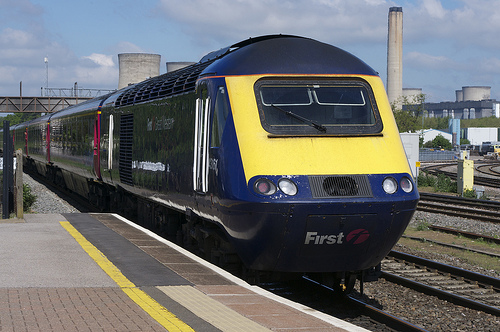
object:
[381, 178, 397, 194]
headlight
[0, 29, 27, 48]
cloud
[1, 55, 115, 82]
cloud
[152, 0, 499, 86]
cloud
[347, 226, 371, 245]
logo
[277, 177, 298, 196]
headlight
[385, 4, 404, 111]
smoke stack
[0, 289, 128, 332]
brick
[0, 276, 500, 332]
ground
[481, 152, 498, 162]
vehicle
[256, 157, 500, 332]
tracks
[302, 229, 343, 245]
letter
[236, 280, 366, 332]
stripe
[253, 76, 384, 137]
windshield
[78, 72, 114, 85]
white clouds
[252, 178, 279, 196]
headlights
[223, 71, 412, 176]
train front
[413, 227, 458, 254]
weeds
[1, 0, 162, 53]
sky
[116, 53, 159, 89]
cooling towers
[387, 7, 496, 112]
power plant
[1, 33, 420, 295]
commuter train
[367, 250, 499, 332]
rails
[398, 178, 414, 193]
lights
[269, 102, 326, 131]
windshield wiper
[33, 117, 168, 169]
reflection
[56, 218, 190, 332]
line